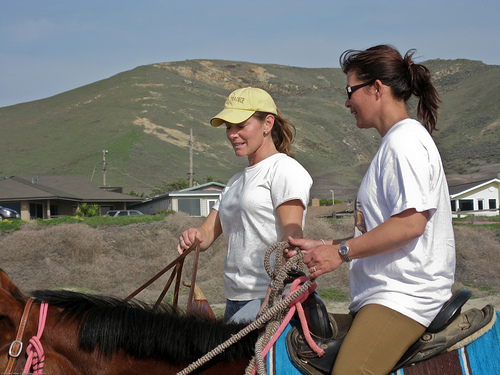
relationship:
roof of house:
[0, 173, 143, 200] [1, 173, 145, 219]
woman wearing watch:
[284, 44, 457, 374] [339, 239, 351, 266]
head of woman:
[345, 45, 413, 128] [284, 44, 457, 374]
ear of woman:
[376, 79, 382, 100] [284, 44, 457, 374]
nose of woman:
[345, 96, 350, 108] [284, 44, 457, 374]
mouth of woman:
[231, 141, 245, 149] [176, 86, 312, 324]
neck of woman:
[375, 101, 410, 139] [284, 44, 457, 374]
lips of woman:
[350, 109, 358, 118] [284, 44, 457, 374]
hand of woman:
[303, 244, 342, 278] [284, 44, 457, 374]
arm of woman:
[177, 173, 240, 256] [176, 86, 312, 324]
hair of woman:
[340, 44, 440, 135] [284, 44, 457, 374]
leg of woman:
[329, 296, 446, 374] [284, 44, 457, 374]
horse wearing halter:
[0, 270, 499, 374] [21, 297, 51, 373]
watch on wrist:
[339, 239, 351, 266] [331, 236, 352, 269]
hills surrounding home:
[0, 58, 498, 219] [447, 178, 500, 216]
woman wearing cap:
[176, 86, 312, 324] [211, 86, 278, 128]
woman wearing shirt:
[176, 86, 312, 324] [213, 153, 313, 301]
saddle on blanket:
[286, 288, 470, 374] [264, 312, 499, 374]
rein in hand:
[115, 236, 202, 313] [177, 226, 201, 258]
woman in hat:
[176, 86, 312, 324] [211, 86, 278, 128]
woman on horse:
[284, 44, 457, 374] [0, 270, 499, 374]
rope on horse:
[173, 240, 316, 374] [0, 270, 499, 374]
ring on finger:
[313, 265, 315, 271] [309, 265, 320, 274]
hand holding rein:
[303, 244, 342, 278] [168, 239, 315, 374]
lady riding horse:
[284, 44, 457, 374] [0, 270, 499, 374]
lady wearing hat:
[176, 86, 312, 324] [211, 86, 278, 128]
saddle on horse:
[286, 288, 470, 374] [0, 270, 499, 374]